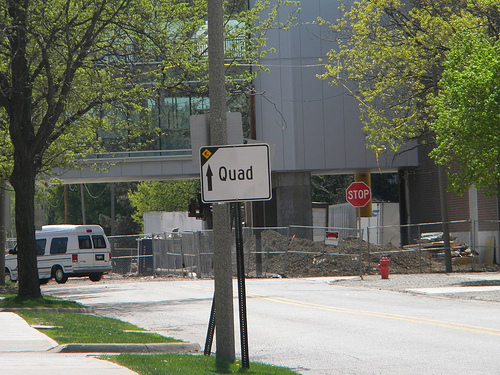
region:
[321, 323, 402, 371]
the street is gray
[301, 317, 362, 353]
the street is gray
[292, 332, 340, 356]
the street is gray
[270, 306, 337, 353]
the street is gray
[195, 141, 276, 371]
a directional sign on the side of the street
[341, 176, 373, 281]
a stop sign at the end of the street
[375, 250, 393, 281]
a red fire hydrant near the street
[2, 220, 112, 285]
a parked white hi top van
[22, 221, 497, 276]
a chain link fence surrounding the building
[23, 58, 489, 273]
the building is a construction site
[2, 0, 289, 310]
a green tree on the swale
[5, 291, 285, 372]
green grass on the swale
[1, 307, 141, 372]
a sidewalk on the side of the street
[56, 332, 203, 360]
a curb through the swale to the street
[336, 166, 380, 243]
A RED AND WHITE STOP SIGN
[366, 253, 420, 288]
A RED FIRE HYDRANT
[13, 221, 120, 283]
A VAN PARKED AT THE CURB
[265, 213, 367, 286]
A CHAIN LINKED FENCE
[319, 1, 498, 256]
A TREE AT A CONSTRUCTION SITE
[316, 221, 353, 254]
A SIGN ON THE FENCE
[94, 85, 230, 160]
WINDOWS ON A BUILDING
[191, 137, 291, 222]
A SIGN WITH THE WORD QUAD ON IT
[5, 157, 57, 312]
A THICK TREE TRUNK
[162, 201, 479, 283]
A CONSTRUCTION SITE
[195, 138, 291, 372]
The street sign is on the grass.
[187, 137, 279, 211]
The sign is black and white.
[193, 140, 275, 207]
The sign reads Quad.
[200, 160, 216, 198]
An arrow is on the sign.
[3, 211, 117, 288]
A white van is parked.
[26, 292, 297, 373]
Grass grows next to the street.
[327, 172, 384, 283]
A stop sign is across the street.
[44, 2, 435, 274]
A building is in the background.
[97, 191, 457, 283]
A fence is in front of the building.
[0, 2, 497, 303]
Trees are in front of the building.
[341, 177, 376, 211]
red stop sign on sidewalk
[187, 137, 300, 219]
Quad sign on side of road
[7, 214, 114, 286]
white van in street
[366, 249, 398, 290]
red fire hydrant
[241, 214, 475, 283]
metal fence in front of construction area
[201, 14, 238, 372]
telephone pole in grass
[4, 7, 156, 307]
tree with green leaves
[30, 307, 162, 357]
green grass by sidewalk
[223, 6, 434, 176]
building in the background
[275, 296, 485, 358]
city street with yellow lines